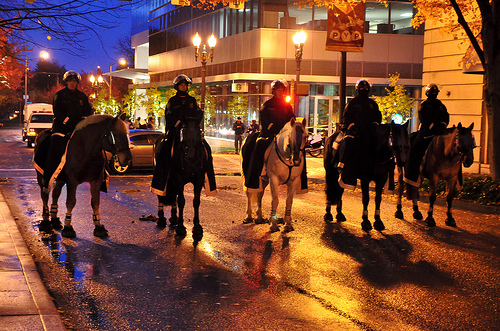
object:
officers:
[158, 73, 213, 158]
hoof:
[372, 219, 387, 231]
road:
[1, 129, 500, 330]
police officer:
[417, 84, 452, 145]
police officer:
[340, 78, 384, 149]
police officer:
[251, 78, 296, 160]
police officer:
[48, 69, 95, 162]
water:
[66, 270, 82, 283]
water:
[114, 195, 128, 203]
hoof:
[189, 224, 206, 235]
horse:
[31, 112, 135, 238]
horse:
[238, 115, 310, 233]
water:
[43, 231, 87, 280]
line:
[0, 204, 52, 330]